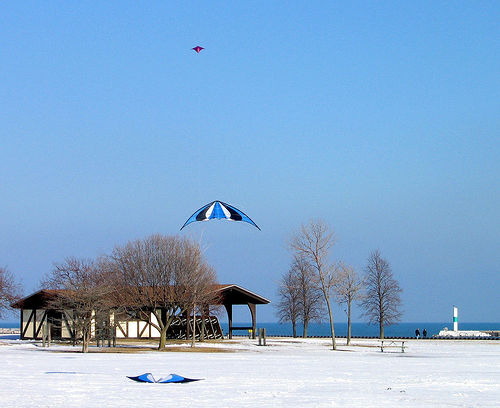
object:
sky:
[0, 0, 499, 331]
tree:
[358, 245, 406, 339]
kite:
[188, 41, 206, 53]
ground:
[236, 341, 390, 394]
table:
[373, 336, 404, 354]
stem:
[324, 302, 346, 351]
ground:
[83, 361, 248, 394]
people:
[407, 324, 432, 340]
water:
[220, 322, 498, 336]